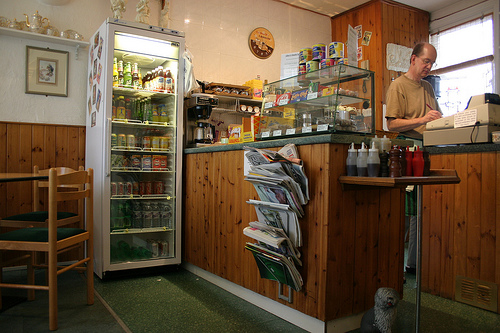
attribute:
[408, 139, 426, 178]
bottle — red 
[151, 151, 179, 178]
can — orange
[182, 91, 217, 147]
coffee maker — silver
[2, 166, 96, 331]
chair — wooden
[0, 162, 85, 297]
chair — wooden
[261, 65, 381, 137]
glass case — Glass 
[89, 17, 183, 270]
fridge — white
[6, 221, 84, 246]
seat — green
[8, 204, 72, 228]
seat — green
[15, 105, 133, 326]
chair. — wooden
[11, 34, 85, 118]
picture — brown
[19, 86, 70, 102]
frame — brown